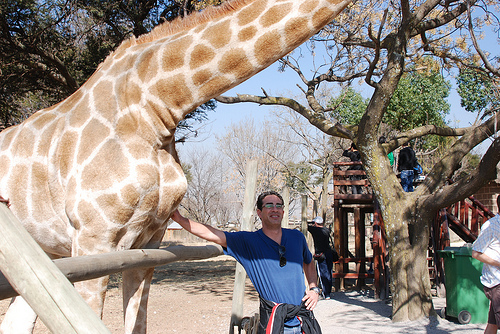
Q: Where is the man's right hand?
A: On the giraffe.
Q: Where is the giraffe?
A: Behind the wooden barrier.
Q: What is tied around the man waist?
A: A jacket.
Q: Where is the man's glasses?
A: On his face.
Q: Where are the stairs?
A: Behind the tree.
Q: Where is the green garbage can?
A: In front of the tree.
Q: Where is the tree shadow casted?
A: To its left.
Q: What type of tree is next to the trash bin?
A: A deciduous tree.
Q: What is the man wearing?
A: A blue shirt.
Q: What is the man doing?
A: Smiling.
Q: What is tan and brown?
A: The giraffe.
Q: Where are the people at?
A: The zoo.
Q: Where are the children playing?
A: On the play structure.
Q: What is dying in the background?
A: The tree.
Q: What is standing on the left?
A: The giraffe.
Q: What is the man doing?
A: Smiling.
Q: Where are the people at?
A: The zoo.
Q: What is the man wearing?
A: A blue shirt.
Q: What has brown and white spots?
A: The giraffe.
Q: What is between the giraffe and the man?
A: The wood barrier.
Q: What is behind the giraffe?
A: Dirt on the ground.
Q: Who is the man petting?
A: A giraffe.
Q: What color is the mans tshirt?
A: Blue.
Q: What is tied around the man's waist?
A: A black jacket.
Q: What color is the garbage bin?
A: Green.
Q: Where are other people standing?
A: On the small bridge.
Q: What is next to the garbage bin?
A: A tree.